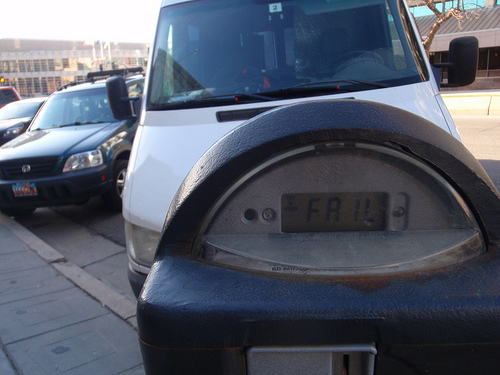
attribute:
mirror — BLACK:
[448, 34, 483, 93]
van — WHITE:
[126, 0, 481, 285]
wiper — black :
[235, 95, 335, 100]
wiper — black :
[259, 84, 341, 94]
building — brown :
[3, 31, 174, 138]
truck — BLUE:
[2, 71, 143, 231]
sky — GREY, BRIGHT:
[1, 10, 169, 55]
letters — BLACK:
[307, 195, 378, 223]